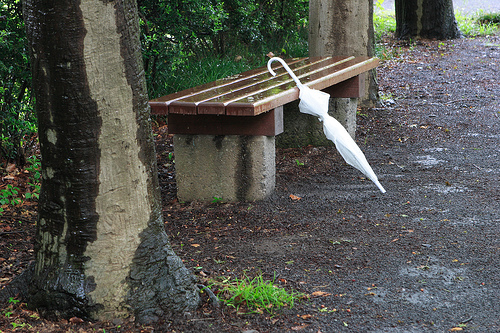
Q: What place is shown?
A: It is a walkway.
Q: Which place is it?
A: It is a walkway.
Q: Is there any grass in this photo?
A: Yes, there is grass.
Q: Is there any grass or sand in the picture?
A: Yes, there is grass.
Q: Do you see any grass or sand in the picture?
A: Yes, there is grass.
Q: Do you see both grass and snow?
A: No, there is grass but no snow.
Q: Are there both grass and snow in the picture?
A: No, there is grass but no snow.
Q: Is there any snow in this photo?
A: No, there is no snow.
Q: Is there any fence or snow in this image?
A: No, there are no snow or fences.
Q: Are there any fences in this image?
A: No, there are no fences.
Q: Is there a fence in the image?
A: No, there are no fences.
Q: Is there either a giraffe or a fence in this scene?
A: No, there are no fences or giraffes.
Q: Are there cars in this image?
A: No, there are no cars.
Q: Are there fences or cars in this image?
A: No, there are no cars or fences.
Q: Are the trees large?
A: Yes, the trees are large.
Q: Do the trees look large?
A: Yes, the trees are large.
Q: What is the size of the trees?
A: The trees are large.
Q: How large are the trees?
A: The trees are large.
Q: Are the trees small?
A: No, the trees are large.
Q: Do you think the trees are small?
A: No, the trees are large.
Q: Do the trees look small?
A: No, the trees are large.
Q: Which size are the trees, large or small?
A: The trees are large.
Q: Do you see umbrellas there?
A: Yes, there is an umbrella.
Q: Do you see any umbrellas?
A: Yes, there is an umbrella.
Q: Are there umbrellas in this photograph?
A: Yes, there is an umbrella.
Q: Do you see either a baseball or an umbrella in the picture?
A: Yes, there is an umbrella.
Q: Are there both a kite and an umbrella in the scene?
A: No, there is an umbrella but no kites.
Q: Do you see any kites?
A: No, there are no kites.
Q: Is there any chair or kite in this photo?
A: No, there are no kites or chairs.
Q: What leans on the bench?
A: The umbrella leans on the bench.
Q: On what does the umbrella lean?
A: The umbrella leans on the bench.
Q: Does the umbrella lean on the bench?
A: Yes, the umbrella leans on the bench.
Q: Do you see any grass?
A: Yes, there is grass.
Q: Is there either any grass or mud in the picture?
A: Yes, there is grass.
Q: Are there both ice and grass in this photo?
A: No, there is grass but no ice.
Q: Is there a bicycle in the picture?
A: No, there are no bicycles.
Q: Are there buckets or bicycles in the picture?
A: No, there are no bicycles or buckets.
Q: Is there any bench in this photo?
A: Yes, there is a bench.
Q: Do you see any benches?
A: Yes, there is a bench.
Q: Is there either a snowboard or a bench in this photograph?
A: Yes, there is a bench.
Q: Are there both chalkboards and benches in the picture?
A: No, there is a bench but no chalkboards.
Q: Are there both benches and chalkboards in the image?
A: No, there is a bench but no chalkboards.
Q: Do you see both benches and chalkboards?
A: No, there is a bench but no chalkboards.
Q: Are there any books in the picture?
A: No, there are no books.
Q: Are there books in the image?
A: No, there are no books.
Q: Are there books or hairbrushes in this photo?
A: No, there are no books or hairbrushes.